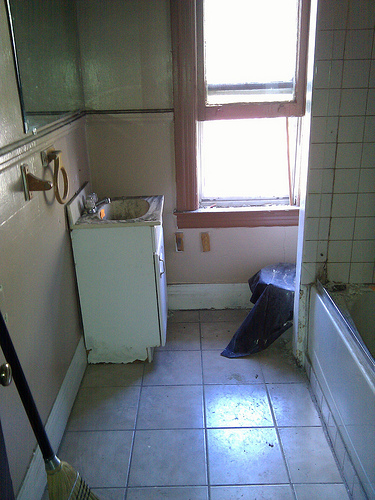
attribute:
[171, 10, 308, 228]
window — sliding, pink, open, large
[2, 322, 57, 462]
handle — dark, black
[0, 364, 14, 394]
knob — metal, shiny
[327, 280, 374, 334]
tub — moldy, dirty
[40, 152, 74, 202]
ring — round, wooden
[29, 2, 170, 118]
mirror — rectangular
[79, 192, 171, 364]
vanity — dirty, moldy, old, rotting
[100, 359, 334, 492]
floor — tiled, shiny, dirty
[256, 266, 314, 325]
cover — black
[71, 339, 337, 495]
floor — tiled